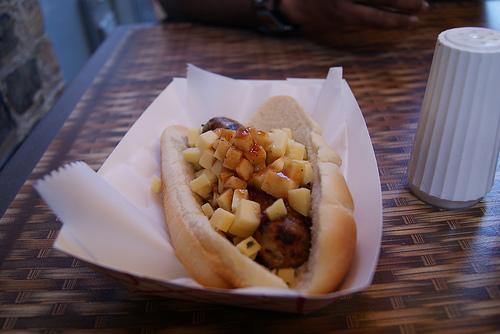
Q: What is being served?
A: A hot dog.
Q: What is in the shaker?
A: Salt.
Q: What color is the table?
A: Brown.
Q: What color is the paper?
A: White.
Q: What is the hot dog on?
A: A bun.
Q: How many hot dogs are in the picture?
A: One.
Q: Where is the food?
A: On the table.